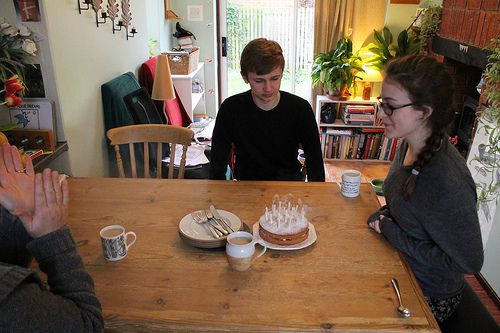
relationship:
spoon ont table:
[390, 278, 411, 318] [130, 147, 440, 332]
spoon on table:
[383, 274, 415, 323] [40, 176, 439, 331]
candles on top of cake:
[263, 196, 305, 226] [256, 199, 312, 245]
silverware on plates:
[177, 202, 244, 239] [176, 205, 245, 245]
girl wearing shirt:
[366, 55, 482, 325] [363, 130, 485, 299]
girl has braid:
[366, 55, 482, 325] [400, 60, 454, 198]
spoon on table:
[390, 278, 411, 318] [40, 176, 439, 331]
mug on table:
[331, 169, 361, 201] [40, 176, 439, 331]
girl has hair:
[366, 55, 482, 325] [385, 54, 456, 199]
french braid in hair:
[397, 55, 455, 199] [385, 54, 456, 199]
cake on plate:
[257, 200, 310, 247] [250, 225, 320, 255]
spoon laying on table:
[390, 278, 411, 318] [0, 178, 442, 330]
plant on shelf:
[306, 33, 368, 103] [311, 94, 402, 169]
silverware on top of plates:
[191, 205, 234, 239] [177, 201, 247, 250]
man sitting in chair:
[204, 36, 329, 181] [223, 148, 309, 181]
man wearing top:
[204, 36, 329, 181] [203, 90, 327, 185]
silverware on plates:
[191, 205, 234, 239] [187, 234, 207, 250]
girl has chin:
[366, 50, 483, 324] [383, 125, 405, 142]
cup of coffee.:
[99, 221, 138, 263] [83, 207, 153, 269]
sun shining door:
[220, 5, 312, 106] [217, 0, 317, 122]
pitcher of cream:
[226, 227, 263, 274] [223, 234, 272, 276]